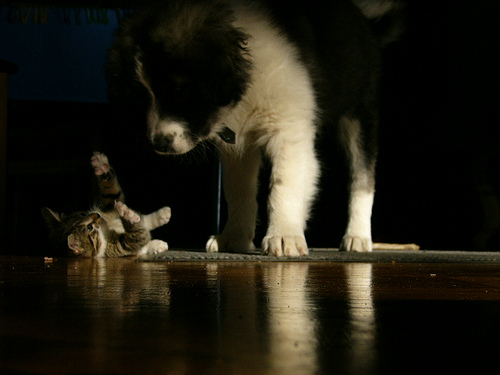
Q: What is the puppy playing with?
A: A kitten.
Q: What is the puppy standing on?
A: A rug.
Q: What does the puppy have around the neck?
A: A collar.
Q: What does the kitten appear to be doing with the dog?
A: Playing.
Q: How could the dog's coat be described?
A: Furry.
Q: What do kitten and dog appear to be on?
A: Area rug.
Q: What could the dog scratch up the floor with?
A: It's claws.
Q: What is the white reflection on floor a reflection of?
A: Dog's legs.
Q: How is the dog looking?
A: Down.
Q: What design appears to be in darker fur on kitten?
A: Stripes.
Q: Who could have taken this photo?
A: Animal's owner.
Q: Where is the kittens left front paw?
A: In air.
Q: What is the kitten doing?
A: Playing.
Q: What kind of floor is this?
A: Hardwood floors.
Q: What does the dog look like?
A: White and black.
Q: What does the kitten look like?
A: Grey white and black.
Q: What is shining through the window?
A: Sunlight.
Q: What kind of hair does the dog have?
A: Long black and white hair.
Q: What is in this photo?
A: Two animals playing.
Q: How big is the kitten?
A: Tiny.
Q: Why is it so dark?
A: Night time.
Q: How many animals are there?
A: Two.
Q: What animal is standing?
A: The dog.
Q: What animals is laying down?
A: The cat.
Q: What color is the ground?
A: Black.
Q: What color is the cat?
A: Gray.